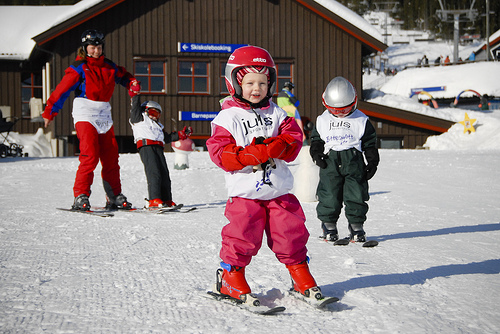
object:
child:
[205, 45, 326, 300]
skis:
[193, 286, 338, 316]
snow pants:
[218, 192, 312, 267]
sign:
[177, 41, 250, 56]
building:
[0, 0, 459, 157]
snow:
[0, 0, 383, 60]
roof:
[1, 0, 390, 73]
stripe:
[29, 0, 387, 54]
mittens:
[222, 132, 299, 167]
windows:
[133, 58, 297, 96]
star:
[457, 114, 477, 137]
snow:
[0, 0, 499, 333]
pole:
[453, 15, 460, 65]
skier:
[309, 77, 381, 247]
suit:
[309, 108, 378, 234]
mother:
[41, 29, 141, 211]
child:
[129, 85, 186, 210]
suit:
[205, 96, 310, 268]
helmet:
[224, 47, 276, 110]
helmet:
[321, 76, 359, 118]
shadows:
[319, 256, 498, 296]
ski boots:
[216, 256, 254, 301]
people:
[387, 50, 477, 77]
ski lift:
[362, 1, 495, 71]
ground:
[1, 0, 500, 333]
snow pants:
[315, 146, 370, 223]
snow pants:
[74, 121, 122, 200]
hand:
[129, 81, 141, 96]